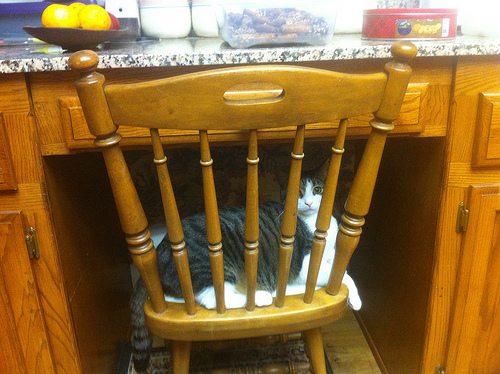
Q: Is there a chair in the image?
A: Yes, there is a chair.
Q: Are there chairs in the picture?
A: Yes, there is a chair.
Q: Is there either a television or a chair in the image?
A: Yes, there is a chair.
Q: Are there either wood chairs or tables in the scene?
A: Yes, there is a wood chair.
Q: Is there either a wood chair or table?
A: Yes, there is a wood chair.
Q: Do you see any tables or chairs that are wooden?
A: Yes, the chair is wooden.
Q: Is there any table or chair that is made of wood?
A: Yes, the chair is made of wood.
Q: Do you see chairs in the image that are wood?
A: Yes, there is a wood chair.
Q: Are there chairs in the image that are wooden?
A: Yes, there is a chair that is wooden.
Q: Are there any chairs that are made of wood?
A: Yes, there is a chair that is made of wood.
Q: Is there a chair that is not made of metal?
A: Yes, there is a chair that is made of wood.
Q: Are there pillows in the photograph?
A: No, there are no pillows.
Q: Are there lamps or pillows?
A: No, there are no pillows or lamps.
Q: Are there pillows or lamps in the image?
A: No, there are no pillows or lamps.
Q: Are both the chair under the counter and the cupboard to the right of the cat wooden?
A: Yes, both the chair and the cupboard are wooden.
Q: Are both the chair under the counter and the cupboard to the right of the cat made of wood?
A: Yes, both the chair and the cupboard are made of wood.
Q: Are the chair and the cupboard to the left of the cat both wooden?
A: Yes, both the chair and the cupboard are wooden.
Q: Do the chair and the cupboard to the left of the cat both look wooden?
A: Yes, both the chair and the cupboard are wooden.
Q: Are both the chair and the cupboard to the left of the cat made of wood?
A: Yes, both the chair and the cupboard are made of wood.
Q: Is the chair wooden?
A: Yes, the chair is wooden.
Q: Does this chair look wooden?
A: Yes, the chair is wooden.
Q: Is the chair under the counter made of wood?
A: Yes, the chair is made of wood.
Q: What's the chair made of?
A: The chair is made of wood.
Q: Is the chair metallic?
A: No, the chair is wooden.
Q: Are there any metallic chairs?
A: No, there is a chair but it is wooden.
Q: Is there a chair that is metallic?
A: No, there is a chair but it is wooden.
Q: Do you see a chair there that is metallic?
A: No, there is a chair but it is wooden.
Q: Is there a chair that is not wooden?
A: No, there is a chair but it is wooden.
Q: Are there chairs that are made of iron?
A: No, there is a chair but it is made of wood.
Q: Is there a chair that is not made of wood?
A: No, there is a chair but it is made of wood.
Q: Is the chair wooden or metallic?
A: The chair is wooden.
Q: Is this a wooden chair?
A: Yes, this is a wooden chair.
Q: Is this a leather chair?
A: No, this is a wooden chair.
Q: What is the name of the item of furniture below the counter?
A: The piece of furniture is a chair.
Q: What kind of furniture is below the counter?
A: The piece of furniture is a chair.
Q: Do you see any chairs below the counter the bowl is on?
A: Yes, there is a chair below the counter.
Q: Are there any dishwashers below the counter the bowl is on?
A: No, there is a chair below the counter.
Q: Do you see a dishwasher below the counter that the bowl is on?
A: No, there is a chair below the counter.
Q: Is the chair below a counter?
A: Yes, the chair is below a counter.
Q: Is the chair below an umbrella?
A: No, the chair is below a counter.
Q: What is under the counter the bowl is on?
A: The chair is under the counter.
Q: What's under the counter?
A: The chair is under the counter.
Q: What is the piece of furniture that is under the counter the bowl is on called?
A: The piece of furniture is a chair.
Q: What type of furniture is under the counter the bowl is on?
A: The piece of furniture is a chair.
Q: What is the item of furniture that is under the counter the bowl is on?
A: The piece of furniture is a chair.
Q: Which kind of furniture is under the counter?
A: The piece of furniture is a chair.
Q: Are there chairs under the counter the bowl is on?
A: Yes, there is a chair under the counter.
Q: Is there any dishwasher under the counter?
A: No, there is a chair under the counter.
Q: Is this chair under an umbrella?
A: No, the chair is under the counter.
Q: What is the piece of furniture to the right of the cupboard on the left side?
A: The piece of furniture is a chair.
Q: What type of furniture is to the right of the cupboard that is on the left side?
A: The piece of furniture is a chair.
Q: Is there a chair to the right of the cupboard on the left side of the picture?
A: Yes, there is a chair to the right of the cupboard.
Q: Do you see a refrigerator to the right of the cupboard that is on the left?
A: No, there is a chair to the right of the cupboard.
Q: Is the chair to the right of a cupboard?
A: Yes, the chair is to the right of a cupboard.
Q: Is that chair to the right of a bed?
A: No, the chair is to the right of a cupboard.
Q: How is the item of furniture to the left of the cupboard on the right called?
A: The piece of furniture is a chair.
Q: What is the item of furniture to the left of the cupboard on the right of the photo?
A: The piece of furniture is a chair.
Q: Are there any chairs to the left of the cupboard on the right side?
A: Yes, there is a chair to the left of the cupboard.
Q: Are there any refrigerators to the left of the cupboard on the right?
A: No, there is a chair to the left of the cupboard.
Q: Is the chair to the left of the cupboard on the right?
A: Yes, the chair is to the left of the cupboard.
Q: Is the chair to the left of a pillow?
A: No, the chair is to the left of the cupboard.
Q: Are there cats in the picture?
A: Yes, there is a cat.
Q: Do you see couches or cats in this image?
A: Yes, there is a cat.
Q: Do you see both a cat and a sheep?
A: No, there is a cat but no sheep.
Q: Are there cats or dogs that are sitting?
A: Yes, the cat is sitting.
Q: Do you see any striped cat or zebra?
A: Yes, there is a striped cat.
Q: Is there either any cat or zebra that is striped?
A: Yes, the cat is striped.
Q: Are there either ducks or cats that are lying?
A: Yes, the cat is lying.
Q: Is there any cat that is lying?
A: Yes, there is a cat that is lying.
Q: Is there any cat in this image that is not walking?
A: Yes, there is a cat that is lying.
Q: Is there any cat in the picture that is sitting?
A: Yes, there is a cat that is sitting.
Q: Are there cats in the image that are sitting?
A: Yes, there is a cat that is sitting.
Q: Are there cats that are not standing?
A: Yes, there is a cat that is sitting.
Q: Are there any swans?
A: No, there are no swans.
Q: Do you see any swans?
A: No, there are no swans.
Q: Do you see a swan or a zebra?
A: No, there are no swans or zebras.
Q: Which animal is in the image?
A: The animal is a cat.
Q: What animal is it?
A: The animal is a cat.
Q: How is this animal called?
A: This is a cat.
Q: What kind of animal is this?
A: This is a cat.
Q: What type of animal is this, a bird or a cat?
A: This is a cat.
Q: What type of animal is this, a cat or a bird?
A: This is a cat.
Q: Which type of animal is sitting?
A: The animal is a cat.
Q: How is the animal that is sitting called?
A: The animal is a cat.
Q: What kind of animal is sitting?
A: The animal is a cat.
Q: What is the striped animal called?
A: The animal is a cat.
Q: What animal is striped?
A: The animal is a cat.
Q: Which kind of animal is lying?
A: The animal is a cat.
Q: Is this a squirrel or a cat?
A: This is a cat.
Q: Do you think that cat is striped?
A: Yes, the cat is striped.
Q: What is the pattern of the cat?
A: The cat is striped.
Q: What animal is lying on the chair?
A: The cat is lying on the chair.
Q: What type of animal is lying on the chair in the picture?
A: The animal is a cat.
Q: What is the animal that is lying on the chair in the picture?
A: The animal is a cat.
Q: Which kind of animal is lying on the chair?
A: The animal is a cat.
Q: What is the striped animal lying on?
A: The cat is lying on the chair.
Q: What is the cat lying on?
A: The cat is lying on the chair.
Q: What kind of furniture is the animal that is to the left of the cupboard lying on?
A: The cat is lying on the chair.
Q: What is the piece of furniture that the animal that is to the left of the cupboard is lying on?
A: The piece of furniture is a chair.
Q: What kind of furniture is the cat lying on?
A: The cat is lying on the chair.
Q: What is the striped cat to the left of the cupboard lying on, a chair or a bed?
A: The cat is lying on a chair.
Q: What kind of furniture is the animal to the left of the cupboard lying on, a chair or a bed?
A: The cat is lying on a chair.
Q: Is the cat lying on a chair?
A: Yes, the cat is lying on a chair.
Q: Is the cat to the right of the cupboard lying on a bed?
A: No, the cat is lying on a chair.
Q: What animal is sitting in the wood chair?
A: The cat is sitting in the chair.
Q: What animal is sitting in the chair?
A: The cat is sitting in the chair.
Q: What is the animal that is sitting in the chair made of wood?
A: The animal is a cat.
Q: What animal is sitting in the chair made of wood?
A: The animal is a cat.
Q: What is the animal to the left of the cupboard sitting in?
A: The cat is sitting in the chair.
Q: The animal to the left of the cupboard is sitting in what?
A: The cat is sitting in the chair.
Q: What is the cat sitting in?
A: The cat is sitting in the chair.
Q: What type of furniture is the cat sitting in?
A: The cat is sitting in the chair.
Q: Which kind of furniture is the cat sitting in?
A: The cat is sitting in the chair.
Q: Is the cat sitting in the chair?
A: Yes, the cat is sitting in the chair.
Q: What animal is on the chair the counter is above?
A: The cat is on the chair.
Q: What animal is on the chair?
A: The cat is on the chair.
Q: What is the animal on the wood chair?
A: The animal is a cat.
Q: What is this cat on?
A: The cat is on the chair.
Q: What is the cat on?
A: The cat is on the chair.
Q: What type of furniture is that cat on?
A: The cat is on the chair.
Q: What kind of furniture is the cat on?
A: The cat is on the chair.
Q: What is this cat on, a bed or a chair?
A: The cat is on a chair.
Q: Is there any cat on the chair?
A: Yes, there is a cat on the chair.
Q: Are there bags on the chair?
A: No, there is a cat on the chair.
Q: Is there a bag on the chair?
A: No, there is a cat on the chair.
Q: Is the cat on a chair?
A: Yes, the cat is on a chair.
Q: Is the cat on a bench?
A: No, the cat is on a chair.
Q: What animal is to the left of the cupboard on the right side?
A: The animal is a cat.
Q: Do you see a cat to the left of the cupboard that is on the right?
A: Yes, there is a cat to the left of the cupboard.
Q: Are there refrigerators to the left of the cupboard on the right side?
A: No, there is a cat to the left of the cupboard.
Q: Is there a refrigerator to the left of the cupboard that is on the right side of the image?
A: No, there is a cat to the left of the cupboard.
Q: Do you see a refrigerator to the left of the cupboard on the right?
A: No, there is a cat to the left of the cupboard.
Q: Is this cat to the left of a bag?
A: No, the cat is to the left of a cupboard.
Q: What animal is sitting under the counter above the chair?
A: The cat is sitting under the counter.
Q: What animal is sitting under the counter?
A: The cat is sitting under the counter.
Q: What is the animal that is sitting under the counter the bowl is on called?
A: The animal is a cat.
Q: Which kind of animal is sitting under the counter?
A: The animal is a cat.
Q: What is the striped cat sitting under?
A: The cat is sitting under the counter.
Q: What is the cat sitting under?
A: The cat is sitting under the counter.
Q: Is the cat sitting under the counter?
A: Yes, the cat is sitting under the counter.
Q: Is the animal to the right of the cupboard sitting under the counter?
A: Yes, the cat is sitting under the counter.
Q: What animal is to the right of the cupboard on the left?
A: The animal is a cat.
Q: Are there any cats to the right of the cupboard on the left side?
A: Yes, there is a cat to the right of the cupboard.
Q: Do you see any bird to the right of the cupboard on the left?
A: No, there is a cat to the right of the cupboard.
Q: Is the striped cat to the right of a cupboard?
A: Yes, the cat is to the right of a cupboard.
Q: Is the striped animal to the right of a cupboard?
A: Yes, the cat is to the right of a cupboard.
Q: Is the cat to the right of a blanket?
A: No, the cat is to the right of a cupboard.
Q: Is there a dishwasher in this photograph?
A: No, there are no dishwashers.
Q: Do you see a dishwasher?
A: No, there are no dishwashers.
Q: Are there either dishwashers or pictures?
A: No, there are no dishwashers or pictures.